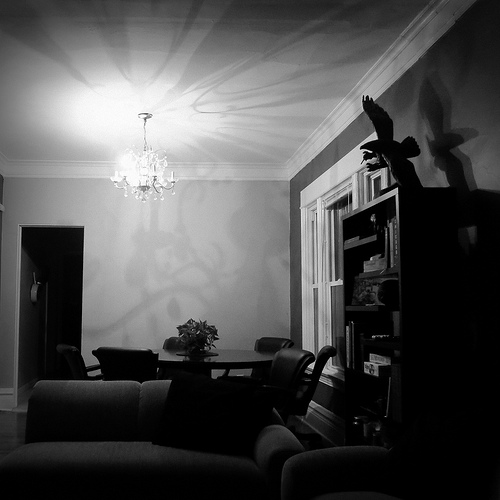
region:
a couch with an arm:
[7, 289, 311, 499]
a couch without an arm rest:
[24, 310, 260, 493]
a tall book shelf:
[284, 162, 497, 429]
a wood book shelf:
[309, 167, 435, 435]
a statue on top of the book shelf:
[343, 142, 433, 254]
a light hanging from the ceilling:
[104, 146, 184, 193]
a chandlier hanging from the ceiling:
[104, 142, 203, 193]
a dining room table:
[75, 281, 297, 392]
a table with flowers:
[57, 270, 308, 427]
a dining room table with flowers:
[122, 275, 309, 404]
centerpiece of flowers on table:
[162, 308, 234, 364]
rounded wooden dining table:
[139, 325, 304, 385]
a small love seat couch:
[36, 372, 321, 488]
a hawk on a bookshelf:
[355, 97, 417, 194]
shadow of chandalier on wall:
[107, 227, 326, 320]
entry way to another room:
[11, 212, 103, 363]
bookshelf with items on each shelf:
[355, 223, 418, 407]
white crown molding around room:
[192, 158, 299, 190]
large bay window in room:
[295, 162, 420, 388]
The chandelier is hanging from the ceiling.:
[108, 104, 208, 206]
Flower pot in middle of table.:
[155, 298, 250, 358]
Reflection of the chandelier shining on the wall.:
[130, 216, 288, 331]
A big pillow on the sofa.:
[156, 378, 282, 453]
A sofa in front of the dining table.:
[19, 373, 306, 491]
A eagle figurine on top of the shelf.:
[335, 97, 433, 227]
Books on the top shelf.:
[375, 211, 397, 275]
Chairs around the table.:
[44, 326, 329, 382]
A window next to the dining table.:
[299, 209, 343, 364]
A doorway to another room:
[4, 212, 109, 387]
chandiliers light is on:
[112, 149, 173, 201]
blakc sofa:
[28, 383, 292, 488]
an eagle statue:
[355, 96, 420, 191]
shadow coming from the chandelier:
[5, 2, 379, 86]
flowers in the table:
[170, 322, 217, 355]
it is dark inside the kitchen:
[19, 227, 81, 378]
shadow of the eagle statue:
[418, 79, 473, 187]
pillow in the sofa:
[160, 379, 262, 457]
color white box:
[363, 360, 390, 377]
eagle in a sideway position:
[365, 96, 420, 193]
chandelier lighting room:
[104, 103, 188, 208]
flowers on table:
[159, 317, 226, 354]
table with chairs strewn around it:
[93, 299, 333, 418]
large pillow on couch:
[164, 363, 261, 443]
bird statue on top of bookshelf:
[355, 94, 457, 181]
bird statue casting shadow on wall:
[415, 72, 480, 184]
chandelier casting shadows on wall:
[42, 175, 288, 335]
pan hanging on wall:
[26, 262, 43, 324]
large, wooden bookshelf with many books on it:
[330, 182, 495, 463]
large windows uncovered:
[295, 152, 381, 384]